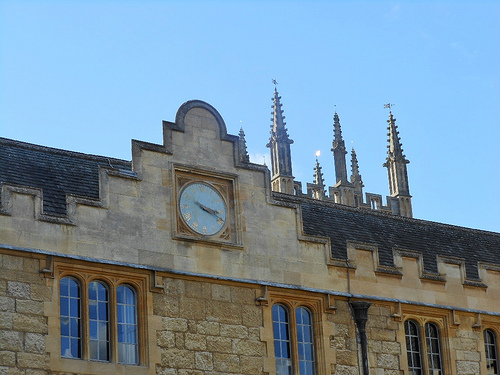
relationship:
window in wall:
[55, 264, 147, 369] [1, 243, 498, 373]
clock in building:
[167, 160, 250, 251] [2, 137, 498, 373]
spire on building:
[266, 72, 298, 192] [0, 78, 500, 373]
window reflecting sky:
[269, 304, 294, 374] [1, 1, 499, 233]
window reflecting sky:
[88, 273, 117, 361] [295, 33, 392, 88]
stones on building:
[152, 276, 272, 373] [0, 78, 500, 373]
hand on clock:
[201, 209, 218, 219] [162, 160, 252, 251]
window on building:
[60, 268, 86, 366] [0, 78, 500, 373]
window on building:
[87, 270, 114, 366] [0, 78, 500, 373]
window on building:
[114, 277, 141, 369] [0, 78, 500, 373]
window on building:
[265, 296, 294, 373] [0, 78, 500, 373]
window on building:
[294, 297, 321, 373] [0, 78, 500, 373]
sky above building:
[1, 1, 499, 233] [241, 75, 413, 218]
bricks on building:
[0, 100, 500, 373] [0, 78, 500, 373]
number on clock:
[198, 186, 206, 193] [177, 176, 229, 238]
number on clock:
[178, 200, 190, 210] [177, 176, 229, 238]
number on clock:
[181, 211, 193, 223] [177, 176, 229, 238]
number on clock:
[187, 221, 199, 231] [177, 176, 229, 238]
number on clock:
[180, 190, 192, 200] [177, 176, 229, 238]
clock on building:
[161, 162, 258, 245] [0, 78, 500, 373]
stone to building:
[457, 313, 479, 368] [0, 78, 500, 373]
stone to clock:
[457, 313, 479, 368] [177, 176, 229, 238]